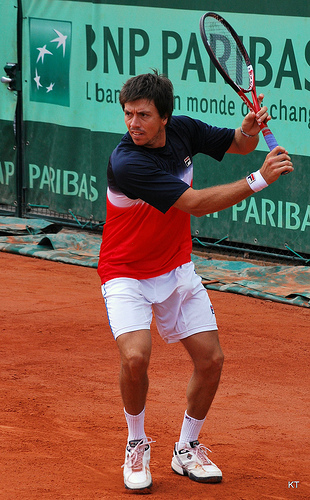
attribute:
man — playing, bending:
[107, 77, 296, 495]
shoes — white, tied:
[119, 443, 221, 490]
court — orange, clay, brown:
[2, 247, 310, 498]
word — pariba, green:
[161, 33, 308, 92]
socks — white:
[122, 412, 210, 452]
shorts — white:
[98, 258, 219, 337]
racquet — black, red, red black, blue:
[192, 13, 292, 172]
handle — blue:
[258, 103, 281, 154]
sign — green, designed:
[3, 4, 308, 244]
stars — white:
[32, 23, 68, 98]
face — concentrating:
[124, 83, 171, 143]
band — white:
[246, 169, 267, 192]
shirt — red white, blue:
[104, 115, 241, 283]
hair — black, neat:
[121, 68, 183, 118]